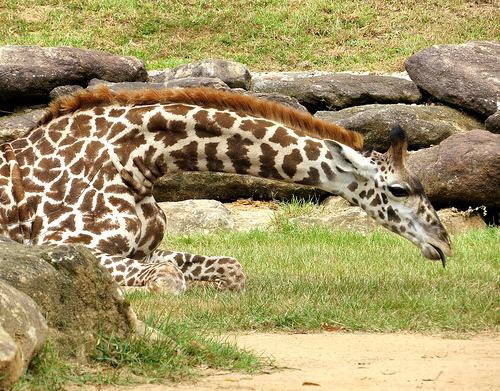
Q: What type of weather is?
A: It is sunny.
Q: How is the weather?
A: It is sunny.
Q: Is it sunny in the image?
A: Yes, it is sunny.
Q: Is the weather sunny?
A: Yes, it is sunny.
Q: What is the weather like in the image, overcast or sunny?
A: It is sunny.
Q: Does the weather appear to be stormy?
A: No, it is sunny.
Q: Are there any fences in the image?
A: No, there are no fences.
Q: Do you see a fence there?
A: No, there are no fences.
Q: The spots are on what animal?
A: The spots are on the giraffe.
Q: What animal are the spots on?
A: The spots are on the giraffe.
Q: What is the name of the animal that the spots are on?
A: The animal is a giraffe.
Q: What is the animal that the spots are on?
A: The animal is a giraffe.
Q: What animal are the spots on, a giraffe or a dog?
A: The spots are on a giraffe.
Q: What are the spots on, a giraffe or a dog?
A: The spots are on a giraffe.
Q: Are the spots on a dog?
A: No, the spots are on the giraffe.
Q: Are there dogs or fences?
A: No, there are no fences or dogs.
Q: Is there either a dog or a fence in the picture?
A: No, there are no fences or dogs.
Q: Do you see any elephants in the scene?
A: No, there are no elephants.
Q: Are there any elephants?
A: No, there are no elephants.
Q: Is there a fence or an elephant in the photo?
A: No, there are no elephants or fences.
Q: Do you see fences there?
A: No, there are no fences.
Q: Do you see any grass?
A: Yes, there is grass.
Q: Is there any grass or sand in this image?
A: Yes, there is grass.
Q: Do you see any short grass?
A: Yes, there is short grass.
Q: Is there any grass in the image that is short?
A: Yes, there is grass that is short.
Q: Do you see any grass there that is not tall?
A: Yes, there is short grass.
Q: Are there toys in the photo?
A: No, there are no toys.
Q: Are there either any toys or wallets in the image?
A: No, there are no toys or wallets.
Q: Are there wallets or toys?
A: No, there are no toys or wallets.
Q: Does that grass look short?
A: Yes, the grass is short.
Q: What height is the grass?
A: The grass is short.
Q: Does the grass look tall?
A: No, the grass is short.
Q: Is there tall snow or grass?
A: No, there is grass but it is short.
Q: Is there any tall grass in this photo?
A: No, there is grass but it is short.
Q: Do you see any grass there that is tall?
A: No, there is grass but it is short.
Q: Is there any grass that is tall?
A: No, there is grass but it is short.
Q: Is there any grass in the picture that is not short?
A: No, there is grass but it is short.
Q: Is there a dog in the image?
A: No, there are no dogs.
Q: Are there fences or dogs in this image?
A: No, there are no dogs or fences.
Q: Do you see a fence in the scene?
A: No, there are no fences.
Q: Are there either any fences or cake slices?
A: No, there are no fences or cake slices.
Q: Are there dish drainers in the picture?
A: No, there are no dish drainers.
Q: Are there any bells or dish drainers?
A: No, there are no dish drainers or bells.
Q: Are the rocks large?
A: Yes, the rocks are large.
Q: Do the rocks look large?
A: Yes, the rocks are large.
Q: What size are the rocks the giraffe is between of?
A: The rocks are large.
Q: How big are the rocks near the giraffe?
A: The rocks are large.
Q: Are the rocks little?
A: No, the rocks are large.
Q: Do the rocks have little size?
A: No, the rocks are large.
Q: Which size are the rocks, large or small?
A: The rocks are large.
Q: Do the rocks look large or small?
A: The rocks are large.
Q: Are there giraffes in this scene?
A: Yes, there is a giraffe.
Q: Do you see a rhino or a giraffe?
A: Yes, there is a giraffe.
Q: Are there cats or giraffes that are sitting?
A: Yes, the giraffe is sitting.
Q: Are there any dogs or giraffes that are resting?
A: Yes, the giraffe is resting.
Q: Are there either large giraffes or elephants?
A: Yes, there is a large giraffe.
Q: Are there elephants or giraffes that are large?
A: Yes, the giraffe is large.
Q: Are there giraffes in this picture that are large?
A: Yes, there is a large giraffe.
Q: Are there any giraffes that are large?
A: Yes, there is a giraffe that is large.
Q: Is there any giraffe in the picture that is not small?
A: Yes, there is a large giraffe.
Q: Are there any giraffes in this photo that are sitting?
A: Yes, there is a giraffe that is sitting.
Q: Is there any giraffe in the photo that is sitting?
A: Yes, there is a giraffe that is sitting.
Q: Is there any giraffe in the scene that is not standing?
A: Yes, there is a giraffe that is sitting.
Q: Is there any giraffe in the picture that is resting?
A: Yes, there is a giraffe that is resting.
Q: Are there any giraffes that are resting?
A: Yes, there is a giraffe that is resting.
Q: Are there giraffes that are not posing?
A: Yes, there is a giraffe that is resting.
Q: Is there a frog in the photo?
A: No, there are no frogs.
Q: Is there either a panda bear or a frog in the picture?
A: No, there are no frogs or panda bears.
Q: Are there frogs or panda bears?
A: No, there are no frogs or panda bears.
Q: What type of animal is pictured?
A: The animal is a giraffe.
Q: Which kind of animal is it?
A: The animal is a giraffe.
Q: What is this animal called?
A: That is a giraffe.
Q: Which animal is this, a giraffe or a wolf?
A: That is a giraffe.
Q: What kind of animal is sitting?
A: The animal is a giraffe.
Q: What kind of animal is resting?
A: The animal is a giraffe.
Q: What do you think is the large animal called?
A: The animal is a giraffe.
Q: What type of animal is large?
A: The animal is a giraffe.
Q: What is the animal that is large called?
A: The animal is a giraffe.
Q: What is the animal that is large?
A: The animal is a giraffe.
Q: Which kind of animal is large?
A: The animal is a giraffe.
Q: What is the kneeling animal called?
A: The animal is a giraffe.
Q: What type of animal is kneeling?
A: The animal is a giraffe.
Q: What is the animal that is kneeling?
A: The animal is a giraffe.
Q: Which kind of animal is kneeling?
A: The animal is a giraffe.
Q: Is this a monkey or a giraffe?
A: This is a giraffe.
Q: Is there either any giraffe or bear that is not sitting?
A: No, there is a giraffe but it is sitting.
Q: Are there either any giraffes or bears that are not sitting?
A: No, there is a giraffe but it is sitting.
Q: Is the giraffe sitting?
A: Yes, the giraffe is sitting.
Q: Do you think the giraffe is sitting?
A: Yes, the giraffe is sitting.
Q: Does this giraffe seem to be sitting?
A: Yes, the giraffe is sitting.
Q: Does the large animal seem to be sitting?
A: Yes, the giraffe is sitting.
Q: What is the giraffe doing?
A: The giraffe is sitting.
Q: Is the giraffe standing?
A: No, the giraffe is sitting.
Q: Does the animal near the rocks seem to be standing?
A: No, the giraffe is sitting.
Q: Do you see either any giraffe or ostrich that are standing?
A: No, there is a giraffe but it is sitting.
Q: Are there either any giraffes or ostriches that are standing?
A: No, there is a giraffe but it is sitting.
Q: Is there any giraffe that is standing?
A: No, there is a giraffe but it is sitting.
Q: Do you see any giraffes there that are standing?
A: No, there is a giraffe but it is sitting.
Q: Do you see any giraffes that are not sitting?
A: No, there is a giraffe but it is sitting.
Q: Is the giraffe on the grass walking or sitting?
A: The giraffe is sitting.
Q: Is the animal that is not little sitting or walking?
A: The giraffe is sitting.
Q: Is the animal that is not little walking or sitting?
A: The giraffe is sitting.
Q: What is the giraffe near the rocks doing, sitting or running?
A: The giraffe is sitting.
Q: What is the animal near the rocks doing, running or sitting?
A: The giraffe is sitting.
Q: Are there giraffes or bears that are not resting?
A: No, there is a giraffe but it is resting.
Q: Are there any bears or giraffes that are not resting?
A: No, there is a giraffe but it is resting.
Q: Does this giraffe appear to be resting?
A: Yes, the giraffe is resting.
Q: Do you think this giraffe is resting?
A: Yes, the giraffe is resting.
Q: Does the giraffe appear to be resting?
A: Yes, the giraffe is resting.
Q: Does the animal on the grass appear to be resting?
A: Yes, the giraffe is resting.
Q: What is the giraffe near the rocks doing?
A: The giraffe is resting.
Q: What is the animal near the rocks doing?
A: The giraffe is resting.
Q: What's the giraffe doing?
A: The giraffe is resting.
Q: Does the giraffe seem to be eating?
A: No, the giraffe is resting.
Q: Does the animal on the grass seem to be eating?
A: No, the giraffe is resting.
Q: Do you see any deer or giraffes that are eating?
A: No, there is a giraffe but it is resting.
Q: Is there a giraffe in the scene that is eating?
A: No, there is a giraffe but it is resting.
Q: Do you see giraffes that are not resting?
A: No, there is a giraffe but it is resting.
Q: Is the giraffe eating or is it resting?
A: The giraffe is resting.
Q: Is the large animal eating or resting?
A: The giraffe is resting.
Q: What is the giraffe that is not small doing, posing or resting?
A: The giraffe is resting.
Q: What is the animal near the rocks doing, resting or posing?
A: The giraffe is resting.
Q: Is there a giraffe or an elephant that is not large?
A: No, there is a giraffe but it is large.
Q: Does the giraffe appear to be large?
A: Yes, the giraffe is large.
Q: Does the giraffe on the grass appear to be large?
A: Yes, the giraffe is large.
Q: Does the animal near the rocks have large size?
A: Yes, the giraffe is large.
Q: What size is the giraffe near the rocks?
A: The giraffe is large.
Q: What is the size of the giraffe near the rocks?
A: The giraffe is large.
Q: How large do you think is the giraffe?
A: The giraffe is large.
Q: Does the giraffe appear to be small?
A: No, the giraffe is large.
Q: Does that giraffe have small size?
A: No, the giraffe is large.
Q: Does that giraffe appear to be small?
A: No, the giraffe is large.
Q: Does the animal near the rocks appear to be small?
A: No, the giraffe is large.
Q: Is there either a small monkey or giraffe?
A: No, there is a giraffe but it is large.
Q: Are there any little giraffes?
A: No, there is a giraffe but it is large.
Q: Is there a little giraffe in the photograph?
A: No, there is a giraffe but it is large.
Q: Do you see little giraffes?
A: No, there is a giraffe but it is large.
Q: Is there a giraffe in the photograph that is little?
A: No, there is a giraffe but it is large.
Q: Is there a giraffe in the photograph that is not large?
A: No, there is a giraffe but it is large.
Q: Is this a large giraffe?
A: Yes, this is a large giraffe.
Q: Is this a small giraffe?
A: No, this is a large giraffe.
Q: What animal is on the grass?
A: The giraffe is on the grass.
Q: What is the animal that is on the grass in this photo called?
A: The animal is a giraffe.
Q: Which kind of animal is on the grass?
A: The animal is a giraffe.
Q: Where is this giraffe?
A: The giraffe is on the grass.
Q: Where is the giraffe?
A: The giraffe is on the grass.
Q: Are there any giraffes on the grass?
A: Yes, there is a giraffe on the grass.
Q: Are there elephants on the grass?
A: No, there is a giraffe on the grass.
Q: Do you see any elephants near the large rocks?
A: No, there is a giraffe near the rocks.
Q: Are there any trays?
A: No, there are no trays.